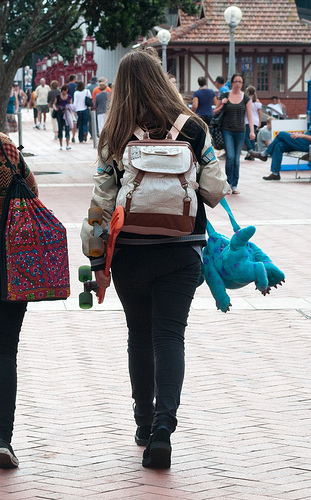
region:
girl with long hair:
[82, 44, 210, 163]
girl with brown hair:
[58, 41, 206, 179]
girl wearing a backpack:
[51, 98, 236, 262]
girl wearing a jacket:
[38, 82, 257, 278]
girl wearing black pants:
[66, 213, 234, 472]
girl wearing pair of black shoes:
[105, 422, 203, 481]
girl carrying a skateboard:
[44, 193, 138, 360]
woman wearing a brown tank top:
[199, 75, 262, 198]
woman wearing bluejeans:
[194, 70, 269, 206]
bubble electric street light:
[192, 7, 252, 134]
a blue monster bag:
[202, 220, 285, 315]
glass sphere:
[222, 3, 242, 25]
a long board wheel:
[77, 264, 91, 282]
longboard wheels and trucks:
[87, 205, 111, 257]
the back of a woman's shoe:
[139, 429, 174, 470]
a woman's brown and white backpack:
[116, 141, 198, 235]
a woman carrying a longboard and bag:
[75, 48, 285, 468]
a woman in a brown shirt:
[213, 72, 254, 194]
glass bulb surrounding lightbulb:
[157, 29, 171, 41]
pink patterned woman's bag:
[0, 161, 70, 299]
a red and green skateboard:
[76, 204, 125, 313]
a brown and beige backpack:
[110, 113, 204, 240]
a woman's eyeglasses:
[232, 80, 244, 84]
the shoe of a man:
[249, 148, 267, 162]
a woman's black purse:
[83, 88, 92, 106]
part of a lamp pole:
[220, 4, 243, 82]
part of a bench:
[283, 149, 310, 178]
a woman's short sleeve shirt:
[191, 87, 217, 115]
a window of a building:
[228, 53, 284, 95]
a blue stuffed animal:
[191, 143, 282, 314]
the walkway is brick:
[224, 386, 265, 463]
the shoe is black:
[140, 416, 182, 473]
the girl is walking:
[93, 47, 206, 468]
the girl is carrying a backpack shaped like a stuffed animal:
[196, 208, 287, 312]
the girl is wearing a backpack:
[124, 136, 200, 239]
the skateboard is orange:
[77, 200, 129, 311]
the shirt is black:
[219, 89, 249, 133]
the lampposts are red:
[30, 37, 102, 73]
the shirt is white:
[72, 88, 90, 110]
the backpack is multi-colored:
[4, 171, 71, 311]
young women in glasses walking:
[210, 68, 265, 205]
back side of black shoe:
[141, 423, 176, 475]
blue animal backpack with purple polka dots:
[189, 216, 294, 318]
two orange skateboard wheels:
[77, 203, 109, 262]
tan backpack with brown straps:
[113, 135, 205, 247]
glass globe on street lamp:
[217, 5, 245, 34]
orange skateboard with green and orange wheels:
[77, 201, 127, 325]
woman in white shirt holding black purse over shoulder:
[69, 77, 96, 152]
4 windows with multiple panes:
[215, 46, 294, 105]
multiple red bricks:
[282, 96, 308, 118]